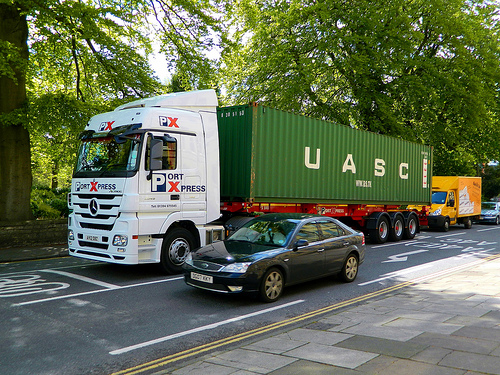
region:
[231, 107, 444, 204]
shipping container on the back of the truck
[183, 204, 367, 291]
car is on the road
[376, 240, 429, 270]
white arrow painted on the road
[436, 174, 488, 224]
yellow van behind the big truck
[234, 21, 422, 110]
trees behind the cars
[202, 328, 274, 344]
yellow lines on the pavement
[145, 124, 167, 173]
mirror on the side of the truck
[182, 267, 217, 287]
license plate on front of the car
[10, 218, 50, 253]
low brick wall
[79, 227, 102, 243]
license plate on the large truck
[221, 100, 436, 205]
a green cargo case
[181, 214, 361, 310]
a black car on a road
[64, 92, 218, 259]
a white front of a truck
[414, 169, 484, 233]
a bright yellow box truck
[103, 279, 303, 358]
a white line on a road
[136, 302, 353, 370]
a double yellow line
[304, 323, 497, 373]
a concrete side walk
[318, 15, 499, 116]
a leafy green tree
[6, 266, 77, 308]
a white symbol on the road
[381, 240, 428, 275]
a white arrow on the road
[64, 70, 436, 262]
This is a large truck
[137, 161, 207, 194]
The truck is owned by Port Xpress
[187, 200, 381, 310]
The black car is next to the big truck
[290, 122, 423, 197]
Letters UASC on the side of the truck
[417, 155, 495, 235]
Yellow truck behind the big truck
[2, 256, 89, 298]
This is the bike lane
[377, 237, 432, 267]
An arrow pointing to the left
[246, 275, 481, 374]
This is the sidewalk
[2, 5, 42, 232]
A big tree trunk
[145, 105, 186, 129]
Company's logo is PX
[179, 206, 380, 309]
car on a street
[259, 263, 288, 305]
front wheel on a car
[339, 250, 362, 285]
rear wheel on a car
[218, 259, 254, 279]
front headlight on a car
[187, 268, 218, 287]
front licence plate on a car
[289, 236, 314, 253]
side rear view mirror on a car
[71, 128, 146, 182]
front windshield on a vehicle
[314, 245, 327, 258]
door handle on a car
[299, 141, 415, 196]
white lettering on a green truck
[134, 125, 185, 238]
side door on a truck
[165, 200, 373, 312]
the car is black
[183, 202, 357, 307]
the car is black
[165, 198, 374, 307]
the car is black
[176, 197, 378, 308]
the car is black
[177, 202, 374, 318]
the car is black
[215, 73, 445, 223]
cargo container is green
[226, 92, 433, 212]
cargo container is green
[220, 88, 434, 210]
cargo container is green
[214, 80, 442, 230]
cargo container is green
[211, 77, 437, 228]
cargo container is green